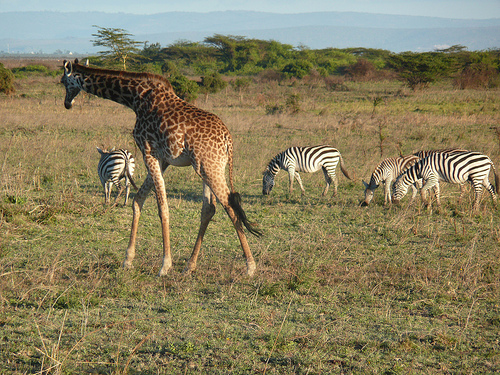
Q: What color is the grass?
A: Green.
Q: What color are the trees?
A: Green.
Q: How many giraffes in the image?
A: One.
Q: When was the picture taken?
A: Daytime.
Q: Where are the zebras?
A: Behind the giraffe.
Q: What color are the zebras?
A: Black and white.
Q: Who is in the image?
A: Zebras and a giraffe.